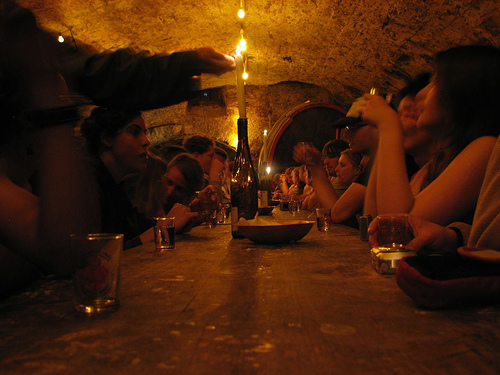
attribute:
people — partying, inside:
[66, 107, 231, 210]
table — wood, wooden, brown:
[242, 272, 329, 305]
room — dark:
[280, 10, 367, 78]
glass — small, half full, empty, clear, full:
[156, 227, 177, 256]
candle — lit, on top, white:
[227, 51, 257, 124]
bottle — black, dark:
[225, 165, 257, 212]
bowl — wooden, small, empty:
[246, 224, 303, 246]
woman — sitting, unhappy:
[396, 52, 474, 221]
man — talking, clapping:
[66, 77, 159, 226]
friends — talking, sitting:
[181, 142, 319, 213]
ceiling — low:
[263, 6, 307, 28]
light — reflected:
[227, 5, 275, 41]